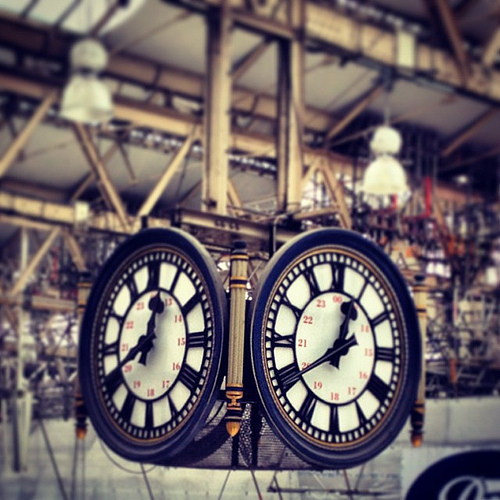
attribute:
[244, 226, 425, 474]
clock — white, black, ornate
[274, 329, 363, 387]
hand — black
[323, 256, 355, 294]
number — roman numeral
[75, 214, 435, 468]
clocks — in a pair, showing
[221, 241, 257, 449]
column — in the middle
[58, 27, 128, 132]
light — hanging, off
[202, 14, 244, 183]
beam — metal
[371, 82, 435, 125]
wires — hanging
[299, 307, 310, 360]
seconds — red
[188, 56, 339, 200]
poles — metal, brown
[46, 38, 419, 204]
objects — white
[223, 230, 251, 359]
pillar — brown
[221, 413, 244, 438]
tip — gold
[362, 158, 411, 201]
shade — white, overhead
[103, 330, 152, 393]
minute hand — black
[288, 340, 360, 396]
minute hand — black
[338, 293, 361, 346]
hour hand — short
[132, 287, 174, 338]
hour hand — short